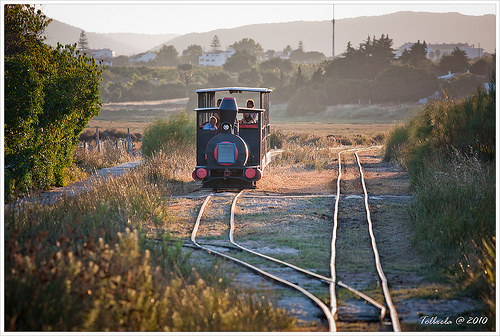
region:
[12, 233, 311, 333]
bush on a hill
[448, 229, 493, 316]
bush on a hill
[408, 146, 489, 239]
bush on a hill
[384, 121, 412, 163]
bush on a hill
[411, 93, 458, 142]
bush on a hill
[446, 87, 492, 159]
bush on a hill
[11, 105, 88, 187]
bush on a hill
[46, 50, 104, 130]
bush on a hill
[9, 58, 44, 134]
bush on a hill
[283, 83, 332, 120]
bush on a hill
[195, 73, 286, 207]
black and red train on tracks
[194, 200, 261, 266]
train tracks before train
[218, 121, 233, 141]
white head light on front of train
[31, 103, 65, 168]
tall green tree on left of photo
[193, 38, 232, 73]
tall white building in the distant middle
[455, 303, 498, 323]
2010 date on right of photo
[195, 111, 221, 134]
person riding in front of train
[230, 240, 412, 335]
two tracks merging into one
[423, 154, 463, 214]
tall weeds on right of photo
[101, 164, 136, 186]
path to the left of the train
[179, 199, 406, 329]
The train tracks on the ground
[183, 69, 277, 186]
The trolley of the tracks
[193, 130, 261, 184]
The front of the trolley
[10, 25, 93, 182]
The leaves of the tree are green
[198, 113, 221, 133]
A man sitting in the front of the trolley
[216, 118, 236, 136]
The head light of the trolley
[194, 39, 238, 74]
The building is the color white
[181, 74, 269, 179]
The trolley is the color black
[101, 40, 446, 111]
The trees are very healthy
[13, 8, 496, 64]
The mountains are very big and vast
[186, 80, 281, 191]
train on the tracks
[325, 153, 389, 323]
track with no train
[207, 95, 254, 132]
people on the train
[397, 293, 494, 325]
artist credit for image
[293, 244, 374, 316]
intersection where tracks cross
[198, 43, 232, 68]
buildings in the distance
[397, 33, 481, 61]
building in the distance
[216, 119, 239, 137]
light on the track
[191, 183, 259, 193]
wheels on the train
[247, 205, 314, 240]
ground between the tracks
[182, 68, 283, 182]
the train on the tracks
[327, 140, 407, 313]
the adjacent tracks are empty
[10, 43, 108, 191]
green bushes beside the train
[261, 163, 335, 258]
grass between the tracks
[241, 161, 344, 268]
the grass is dry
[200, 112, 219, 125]
passengers on the train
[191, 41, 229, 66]
white building in the background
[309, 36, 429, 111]
tall pine trees in the background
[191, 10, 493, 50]
the large hill in the background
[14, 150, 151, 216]
the path beside the bushes